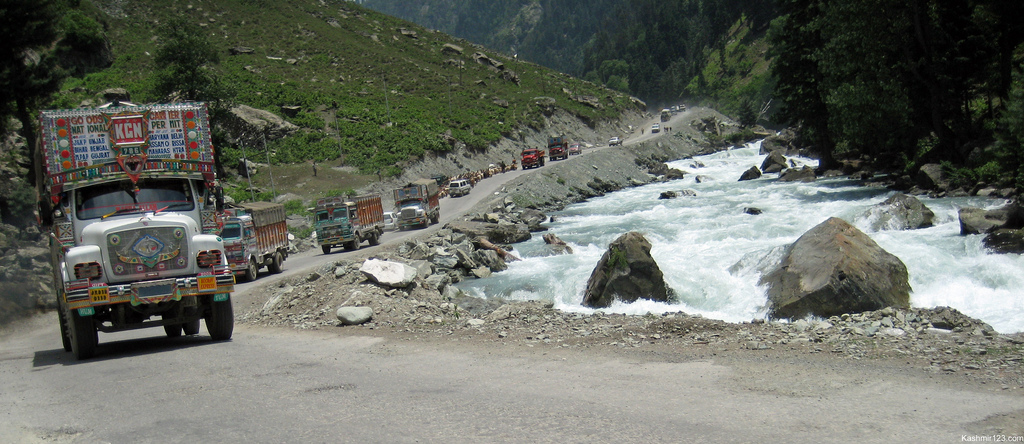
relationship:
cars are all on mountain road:
[298, 178, 446, 256] [0, 101, 1016, 444]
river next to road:
[583, 128, 821, 334] [231, 108, 497, 431]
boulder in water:
[718, 213, 907, 325] [553, 147, 850, 303]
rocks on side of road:
[374, 175, 591, 346] [186, 169, 532, 440]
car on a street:
[15, 95, 283, 415] [77, 197, 508, 435]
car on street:
[216, 192, 305, 290] [15, 108, 1003, 439]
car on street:
[380, 164, 445, 238] [0, 75, 1022, 439]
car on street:
[432, 149, 484, 208] [4, 119, 735, 437]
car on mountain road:
[480, 155, 511, 184] [0, 101, 1016, 444]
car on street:
[491, 142, 526, 179] [15, 108, 1003, 439]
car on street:
[562, 119, 595, 163] [0, 75, 1022, 439]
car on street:
[609, 132, 629, 146] [15, 108, 1003, 439]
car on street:
[655, 93, 682, 130] [15, 108, 1003, 439]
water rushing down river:
[540, 89, 1011, 345] [443, 78, 1012, 424]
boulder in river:
[743, 212, 942, 333] [458, 95, 1016, 405]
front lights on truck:
[60, 246, 227, 286] [33, 71, 256, 365]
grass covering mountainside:
[0, 4, 612, 311] [13, 15, 655, 361]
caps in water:
[557, 147, 998, 349] [497, 80, 1012, 372]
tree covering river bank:
[648, 6, 1016, 227] [410, 52, 1011, 400]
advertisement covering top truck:
[48, 80, 204, 189] [13, 67, 305, 402]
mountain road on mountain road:
[0, 101, 1016, 444] [7, 88, 1017, 439]